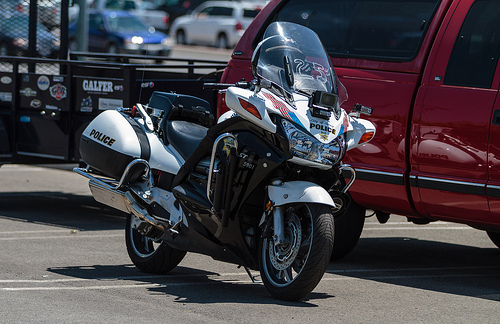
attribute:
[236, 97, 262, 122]
lights — orange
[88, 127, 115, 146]
word — police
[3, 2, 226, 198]
trailer — black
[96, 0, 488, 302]
truck — red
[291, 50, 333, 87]
25 — written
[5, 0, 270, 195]
trailer — black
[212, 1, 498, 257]
truck. — red, parked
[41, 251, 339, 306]
shadow — small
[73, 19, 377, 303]
motorcycle — police, white, black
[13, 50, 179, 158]
trailer — black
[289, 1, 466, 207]
truck — black, red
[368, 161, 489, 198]
trim — black